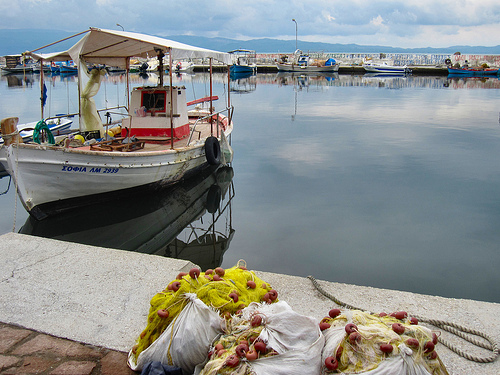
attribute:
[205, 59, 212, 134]
pole — brown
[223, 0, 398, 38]
clouds — large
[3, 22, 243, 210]
boat — white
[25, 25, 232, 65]
roof — on the boat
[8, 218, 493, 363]
pavement — gray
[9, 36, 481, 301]
boats — scene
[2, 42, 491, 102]
boats — row